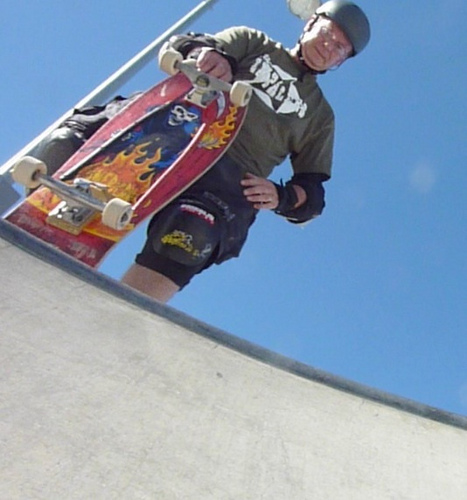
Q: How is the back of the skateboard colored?
A: Red, blue, and orange.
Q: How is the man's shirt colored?
A: Gray and white.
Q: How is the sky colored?
A: Blue.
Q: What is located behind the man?
A: Pole.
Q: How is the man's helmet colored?
A: Gray.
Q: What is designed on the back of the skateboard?
A: A ghost and red flames.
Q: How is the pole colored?
A: Gray.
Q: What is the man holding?
A: A skateboard.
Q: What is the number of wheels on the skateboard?
A: Four.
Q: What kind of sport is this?
A: Skateboarding.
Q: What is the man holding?
A: Skateboard.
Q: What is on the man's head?
A: Helmet.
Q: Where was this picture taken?
A: Skate ramp.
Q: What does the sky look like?
A: Clear and blue.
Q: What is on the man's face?
A: Glasses.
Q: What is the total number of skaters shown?
A: 1.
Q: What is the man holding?
A: A skateboard.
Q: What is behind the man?
A: A light pole.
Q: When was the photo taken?
A: During the day.